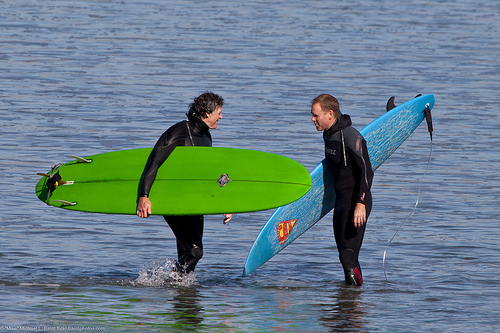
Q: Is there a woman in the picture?
A: No, there are no women.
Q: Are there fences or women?
A: No, there are no women or fences.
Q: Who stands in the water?
A: The man stands in the water.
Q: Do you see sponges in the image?
A: No, there are no sponges.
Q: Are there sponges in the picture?
A: No, there are no sponges.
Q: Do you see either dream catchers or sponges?
A: No, there are no sponges or dream catchers.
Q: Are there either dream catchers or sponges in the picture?
A: No, there are no sponges or dream catchers.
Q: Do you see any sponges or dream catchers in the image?
A: No, there are no sponges or dream catchers.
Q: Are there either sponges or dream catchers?
A: No, there are no sponges or dream catchers.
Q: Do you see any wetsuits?
A: Yes, there is a wetsuit.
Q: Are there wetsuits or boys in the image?
A: Yes, there is a wetsuit.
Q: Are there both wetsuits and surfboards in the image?
A: Yes, there are both a wetsuit and a surfboard.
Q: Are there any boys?
A: No, there are no boys.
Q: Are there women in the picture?
A: No, there are no women.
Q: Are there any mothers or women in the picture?
A: No, there are no women or mothers.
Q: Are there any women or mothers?
A: No, there are no women or mothers.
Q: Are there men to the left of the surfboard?
A: Yes, there is a man to the left of the surfboard.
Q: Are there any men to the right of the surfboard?
A: No, the man is to the left of the surfboard.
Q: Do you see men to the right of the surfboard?
A: No, the man is to the left of the surfboard.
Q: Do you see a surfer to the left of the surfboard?
A: No, there is a man to the left of the surfboard.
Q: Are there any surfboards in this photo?
A: Yes, there is a surfboard.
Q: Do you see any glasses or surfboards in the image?
A: Yes, there is a surfboard.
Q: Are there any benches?
A: No, there are no benches.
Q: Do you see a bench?
A: No, there are no benches.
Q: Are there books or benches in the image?
A: No, there are no benches or books.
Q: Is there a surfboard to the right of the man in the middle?
A: Yes, there is a surfboard to the right of the man.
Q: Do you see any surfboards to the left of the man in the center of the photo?
A: No, the surfboard is to the right of the man.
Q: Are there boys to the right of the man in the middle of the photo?
A: No, there is a surfboard to the right of the man.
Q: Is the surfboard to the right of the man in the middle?
A: Yes, the surfboard is to the right of the man.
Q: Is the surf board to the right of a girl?
A: No, the surf board is to the right of the man.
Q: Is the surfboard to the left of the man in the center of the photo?
A: No, the surfboard is to the right of the man.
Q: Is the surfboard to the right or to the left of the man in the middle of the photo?
A: The surfboard is to the right of the man.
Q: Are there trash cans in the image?
A: No, there are no trash cans.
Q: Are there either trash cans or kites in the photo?
A: No, there are no trash cans or kites.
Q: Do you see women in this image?
A: No, there are no women.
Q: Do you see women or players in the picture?
A: No, there are no women or players.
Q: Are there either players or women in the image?
A: No, there are no women or players.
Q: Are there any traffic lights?
A: No, there are no traffic lights.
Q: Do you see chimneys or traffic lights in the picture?
A: No, there are no traffic lights or chimneys.